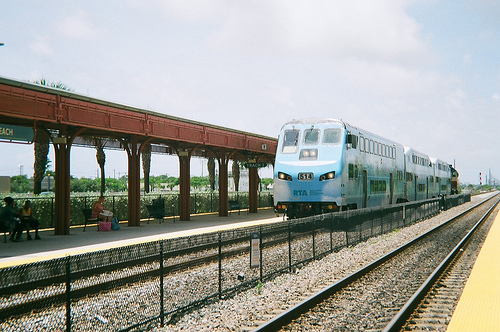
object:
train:
[271, 117, 459, 229]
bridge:
[0, 73, 277, 163]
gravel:
[1, 193, 498, 331]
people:
[90, 195, 120, 231]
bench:
[80, 206, 101, 234]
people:
[22, 200, 40, 240]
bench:
[0, 211, 41, 243]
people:
[0, 195, 21, 243]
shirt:
[22, 205, 32, 218]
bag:
[100, 221, 114, 231]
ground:
[0, 203, 288, 269]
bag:
[113, 216, 120, 230]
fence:
[0, 191, 274, 231]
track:
[0, 188, 499, 331]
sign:
[248, 230, 264, 268]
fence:
[0, 192, 473, 331]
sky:
[187, 0, 500, 117]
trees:
[19, 78, 80, 196]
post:
[217, 230, 222, 300]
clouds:
[384, 4, 468, 114]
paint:
[0, 245, 77, 268]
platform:
[0, 208, 280, 273]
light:
[322, 169, 335, 180]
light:
[278, 171, 284, 179]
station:
[0, 74, 500, 332]